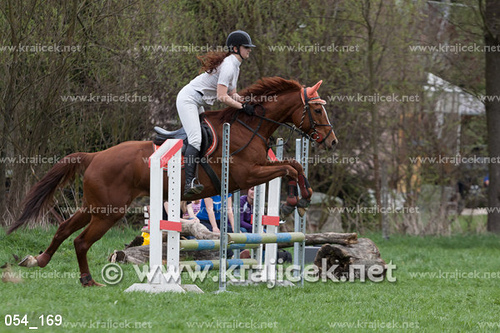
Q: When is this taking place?
A: Daytime.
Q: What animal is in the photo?
A: Horse.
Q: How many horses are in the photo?
A: One.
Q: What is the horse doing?
A: Jumping.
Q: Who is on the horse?
A: Jockey.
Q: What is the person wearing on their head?
A: Hat.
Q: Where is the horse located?
A: Field.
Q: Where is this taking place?
A: On a Ranch.